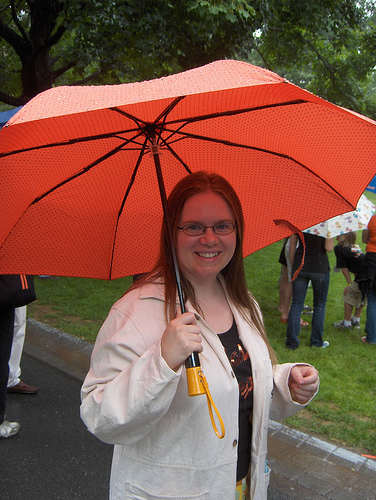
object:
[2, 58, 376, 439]
umbrella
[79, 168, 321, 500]
woman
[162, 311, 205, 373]
hands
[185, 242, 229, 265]
smile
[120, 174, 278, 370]
hair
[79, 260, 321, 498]
jacket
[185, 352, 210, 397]
handle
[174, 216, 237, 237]
glass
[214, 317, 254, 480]
top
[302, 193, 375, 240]
umbrella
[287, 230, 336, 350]
lady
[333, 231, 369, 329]
boy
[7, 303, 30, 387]
pant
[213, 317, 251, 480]
shirt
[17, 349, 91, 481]
road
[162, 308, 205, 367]
hand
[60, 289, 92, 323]
grass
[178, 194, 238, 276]
face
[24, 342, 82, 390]
edge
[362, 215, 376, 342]
people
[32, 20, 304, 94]
rain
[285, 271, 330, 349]
jean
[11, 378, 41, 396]
shoe